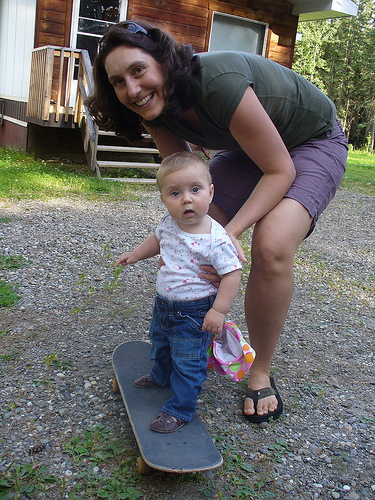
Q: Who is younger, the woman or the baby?
A: The baby is younger than the woman.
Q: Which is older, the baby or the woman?
A: The woman is older than the baby.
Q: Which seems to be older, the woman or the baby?
A: The woman is older than the baby.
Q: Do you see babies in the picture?
A: Yes, there is a baby.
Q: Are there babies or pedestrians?
A: Yes, there is a baby.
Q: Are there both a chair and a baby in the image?
A: No, there is a baby but no chairs.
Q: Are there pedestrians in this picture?
A: No, there are no pedestrians.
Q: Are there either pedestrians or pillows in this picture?
A: No, there are no pedestrians or pillows.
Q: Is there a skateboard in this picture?
A: Yes, there is a skateboard.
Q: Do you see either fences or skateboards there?
A: Yes, there is a skateboard.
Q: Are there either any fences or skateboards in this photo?
A: Yes, there is a skateboard.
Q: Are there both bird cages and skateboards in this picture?
A: No, there is a skateboard but no bird cages.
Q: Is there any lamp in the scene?
A: No, there are no lamps.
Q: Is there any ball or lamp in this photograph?
A: No, there are no lamps or balls.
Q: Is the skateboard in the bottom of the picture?
A: Yes, the skateboard is in the bottom of the image.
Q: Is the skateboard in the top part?
A: No, the skateboard is in the bottom of the image.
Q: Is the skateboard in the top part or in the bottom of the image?
A: The skateboard is in the bottom of the image.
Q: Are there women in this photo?
A: Yes, there is a woman.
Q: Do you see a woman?
A: Yes, there is a woman.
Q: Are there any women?
A: Yes, there is a woman.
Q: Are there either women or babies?
A: Yes, there is a woman.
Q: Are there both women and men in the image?
A: No, there is a woman but no men.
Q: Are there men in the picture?
A: No, there are no men.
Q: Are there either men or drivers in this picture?
A: No, there are no men or drivers.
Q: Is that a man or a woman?
A: That is a woman.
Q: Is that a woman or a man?
A: That is a woman.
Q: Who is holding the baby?
A: The woman is holding the baby.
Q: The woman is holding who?
A: The woman is holding the baby.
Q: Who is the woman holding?
A: The woman is holding the baby.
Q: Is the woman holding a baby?
A: Yes, the woman is holding a baby.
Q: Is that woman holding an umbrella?
A: No, the woman is holding a baby.